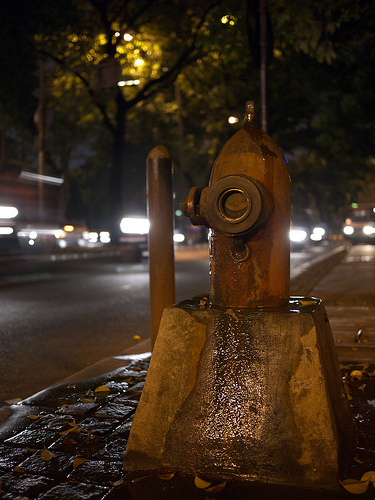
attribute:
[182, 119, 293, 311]
hydrant — rusty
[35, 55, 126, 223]
sign — business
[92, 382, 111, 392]
leaf — yellow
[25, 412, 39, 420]
leaf — yellow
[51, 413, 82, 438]
leaf — yellow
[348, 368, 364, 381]
leaf — yellow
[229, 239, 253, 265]
ring — metal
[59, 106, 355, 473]
structure — wet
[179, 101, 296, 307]
fire hydrant — rusted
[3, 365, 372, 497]
ground — wet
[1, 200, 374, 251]
lights — on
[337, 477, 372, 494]
leaf — yellow